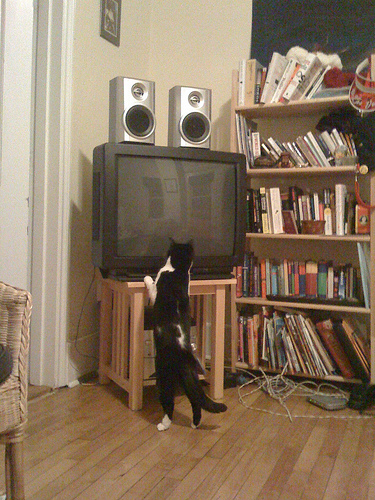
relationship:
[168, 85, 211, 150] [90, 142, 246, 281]
speakers on television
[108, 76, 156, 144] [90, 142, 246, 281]
speakers on television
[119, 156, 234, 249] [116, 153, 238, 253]
room reflection on tv screen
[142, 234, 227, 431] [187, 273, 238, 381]
cat climbing up tv stand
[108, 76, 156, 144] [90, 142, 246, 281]
speakers on top of television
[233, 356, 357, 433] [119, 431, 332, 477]
cords laying on floor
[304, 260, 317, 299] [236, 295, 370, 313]
book on shelf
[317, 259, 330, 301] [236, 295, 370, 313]
book on shelf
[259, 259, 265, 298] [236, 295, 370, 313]
book on shelf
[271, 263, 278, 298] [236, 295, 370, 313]
book on shelf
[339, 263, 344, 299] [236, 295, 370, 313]
book on shelf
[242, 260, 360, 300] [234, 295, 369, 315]
book on shelf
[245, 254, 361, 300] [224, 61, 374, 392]
books on a case shelf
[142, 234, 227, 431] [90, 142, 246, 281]
cat looking at television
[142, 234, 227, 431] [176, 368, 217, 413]
cat has black tail